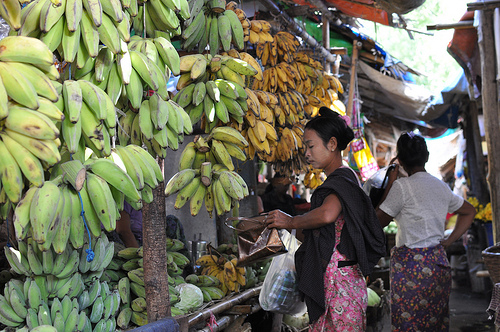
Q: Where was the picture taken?
A: In a market.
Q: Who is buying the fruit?
A: A woman with purse.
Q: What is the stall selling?
A: Bananas.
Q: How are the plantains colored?
A: Yellow and black.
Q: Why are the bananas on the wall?
A: To be sold.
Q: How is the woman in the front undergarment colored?
A: Pink.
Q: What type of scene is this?
A: Market scene.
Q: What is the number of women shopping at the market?
A: Two.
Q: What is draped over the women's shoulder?
A: Blanket.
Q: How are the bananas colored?
A: Green.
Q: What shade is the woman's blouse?
A: White.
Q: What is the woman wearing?
A: Skirt.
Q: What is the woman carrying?
A: Bag.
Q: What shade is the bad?
A: White.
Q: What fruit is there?
A: Bananas.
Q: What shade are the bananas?
A: Green.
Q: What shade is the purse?
A: Pink.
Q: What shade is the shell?
A: Black.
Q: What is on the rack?
A: Bananas.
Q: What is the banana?
A: Yellow.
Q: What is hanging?
A: The banana.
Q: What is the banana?
A: Delicious.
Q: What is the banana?
A: Healthy.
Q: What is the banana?
A: The market.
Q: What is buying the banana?
A: The lady.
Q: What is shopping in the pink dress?
A: The woman.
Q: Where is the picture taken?
A: A market.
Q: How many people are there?
A: Three.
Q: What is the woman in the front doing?
A: Buying produce.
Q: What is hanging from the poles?
A: Plantains.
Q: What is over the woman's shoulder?
A: A blanket.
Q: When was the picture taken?
A: At daytime.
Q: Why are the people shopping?
A: For food.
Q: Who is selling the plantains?
A: A woman in the booth.